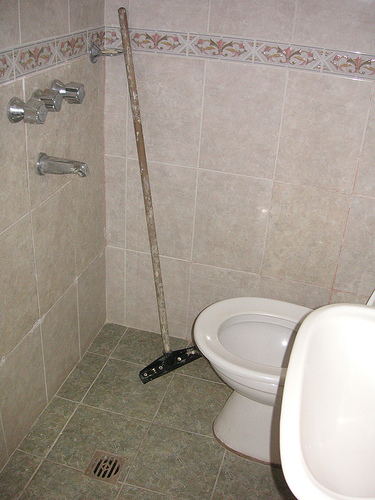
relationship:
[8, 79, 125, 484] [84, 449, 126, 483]
shower has drain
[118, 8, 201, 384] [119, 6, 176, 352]
paint scraper has handle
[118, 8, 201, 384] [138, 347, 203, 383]
paint scraper has bottom piece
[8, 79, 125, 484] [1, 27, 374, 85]
shower has tile lining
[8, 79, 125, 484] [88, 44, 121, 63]
shower has towel rack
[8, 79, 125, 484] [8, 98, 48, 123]
shower has temperature knob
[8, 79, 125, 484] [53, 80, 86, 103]
shower has temperature knob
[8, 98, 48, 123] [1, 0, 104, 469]
temperature knob connected to wall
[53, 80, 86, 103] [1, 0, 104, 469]
temperature knob connected to wall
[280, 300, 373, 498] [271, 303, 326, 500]
sink has shadow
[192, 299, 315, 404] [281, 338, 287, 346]
toilet bowl has glare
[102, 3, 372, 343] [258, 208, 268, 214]
wall has glare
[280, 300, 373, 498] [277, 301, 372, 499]
sink has lip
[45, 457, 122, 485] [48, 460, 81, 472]
grout has red stain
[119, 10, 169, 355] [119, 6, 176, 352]
paint covers handle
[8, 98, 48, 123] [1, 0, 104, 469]
temperature knob inside of wall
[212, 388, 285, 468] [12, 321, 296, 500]
toilet base on top of floor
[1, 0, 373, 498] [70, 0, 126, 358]
bathroom contains corner tiles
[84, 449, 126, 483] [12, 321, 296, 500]
drain on top of floor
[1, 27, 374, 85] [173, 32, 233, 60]
tile lining has pattern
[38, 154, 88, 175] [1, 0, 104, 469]
faucet inside of wall